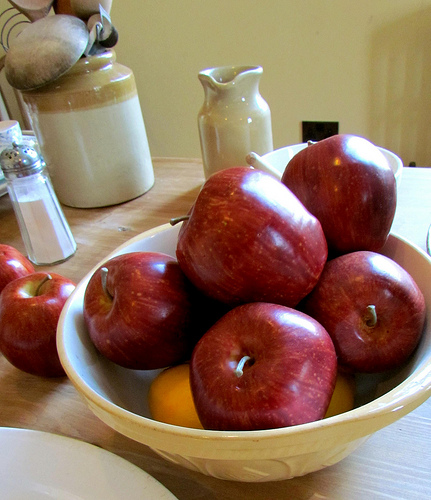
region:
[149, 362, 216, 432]
Orange in the bowl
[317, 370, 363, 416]
Orange in the bowl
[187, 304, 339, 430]
Apple in the bowl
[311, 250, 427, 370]
Apple in the bowl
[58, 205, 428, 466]
Bowl on the table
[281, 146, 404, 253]
Apple in the bowl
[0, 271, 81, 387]
Apple on the table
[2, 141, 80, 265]
Salt shaker on the table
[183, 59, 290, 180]
Pitcher on the table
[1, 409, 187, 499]
Plate on the table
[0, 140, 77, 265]
White salt shaker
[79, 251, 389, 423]
Apples are covering oranges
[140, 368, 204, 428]
Orange beneath two apples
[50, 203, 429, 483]
Fruits are in ceramic bowl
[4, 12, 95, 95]
Soup ladle in jar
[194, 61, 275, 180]
Glass cup for pouring cream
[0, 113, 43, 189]
Tea cup sitting on plate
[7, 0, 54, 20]
Wooden spoon behind ladle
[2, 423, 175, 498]
White plate in front of bowl of fruit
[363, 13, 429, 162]
Shadow of chair on wall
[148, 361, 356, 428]
Two pieces of yellow food sitting beneath apples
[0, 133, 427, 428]
Seven shiny red apples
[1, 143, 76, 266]
Glass salt shaker with a silver cap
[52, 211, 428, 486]
Yellow ceramic bowl filled with fruit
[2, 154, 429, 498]
Light brown wooden table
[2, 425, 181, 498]
Edge of a round white plate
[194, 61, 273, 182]
Cream color ceramic pitcher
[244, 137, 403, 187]
Wooden handle sticking out of a bowl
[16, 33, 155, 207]
Light colored ceramic jar filled with kitchen utencils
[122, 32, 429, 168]
Mustard colored kitchen wall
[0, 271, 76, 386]
The apple is red.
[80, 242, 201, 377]
The apple is red.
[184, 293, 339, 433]
The apple is red.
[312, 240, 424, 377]
The apple is red.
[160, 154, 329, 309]
The apple is red.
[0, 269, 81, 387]
The apple has a stem.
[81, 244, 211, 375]
The apple has a stem.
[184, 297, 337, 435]
The apple has a stem.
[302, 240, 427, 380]
The apple has a stem.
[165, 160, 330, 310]
The apple has a stem.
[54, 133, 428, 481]
a bowl of fresh fruit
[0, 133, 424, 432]
lots of fresh fruit setting on table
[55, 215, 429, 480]
white fruit bowl set on table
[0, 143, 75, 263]
salt shaker is behind apples on table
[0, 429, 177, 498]
white plate or dish at edge of photo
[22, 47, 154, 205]
antique jug repurposed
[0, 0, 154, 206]
jug has many utencils in it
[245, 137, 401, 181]
wooden kitchen spoon sticking out of a bowl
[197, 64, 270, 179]
milk jug is setting on table and matches utencil holder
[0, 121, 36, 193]
tea cup and saucer